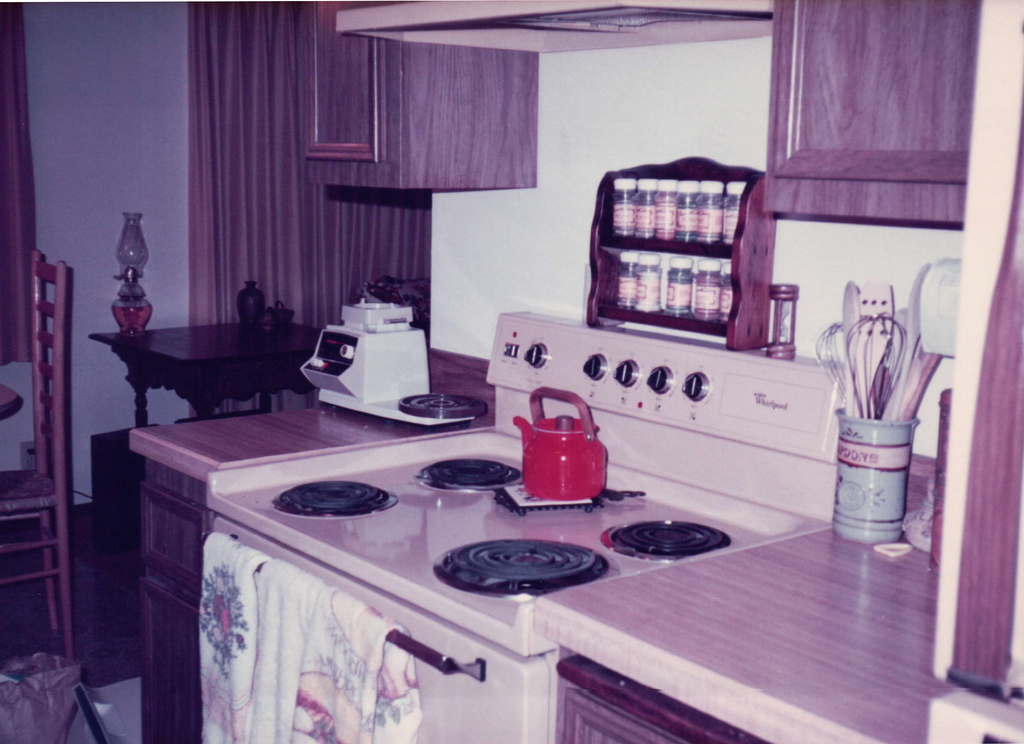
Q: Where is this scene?
A: Kitchen.